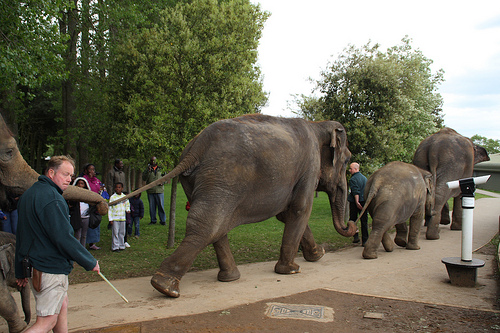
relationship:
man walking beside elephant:
[13, 158, 108, 331] [5, 120, 114, 331]